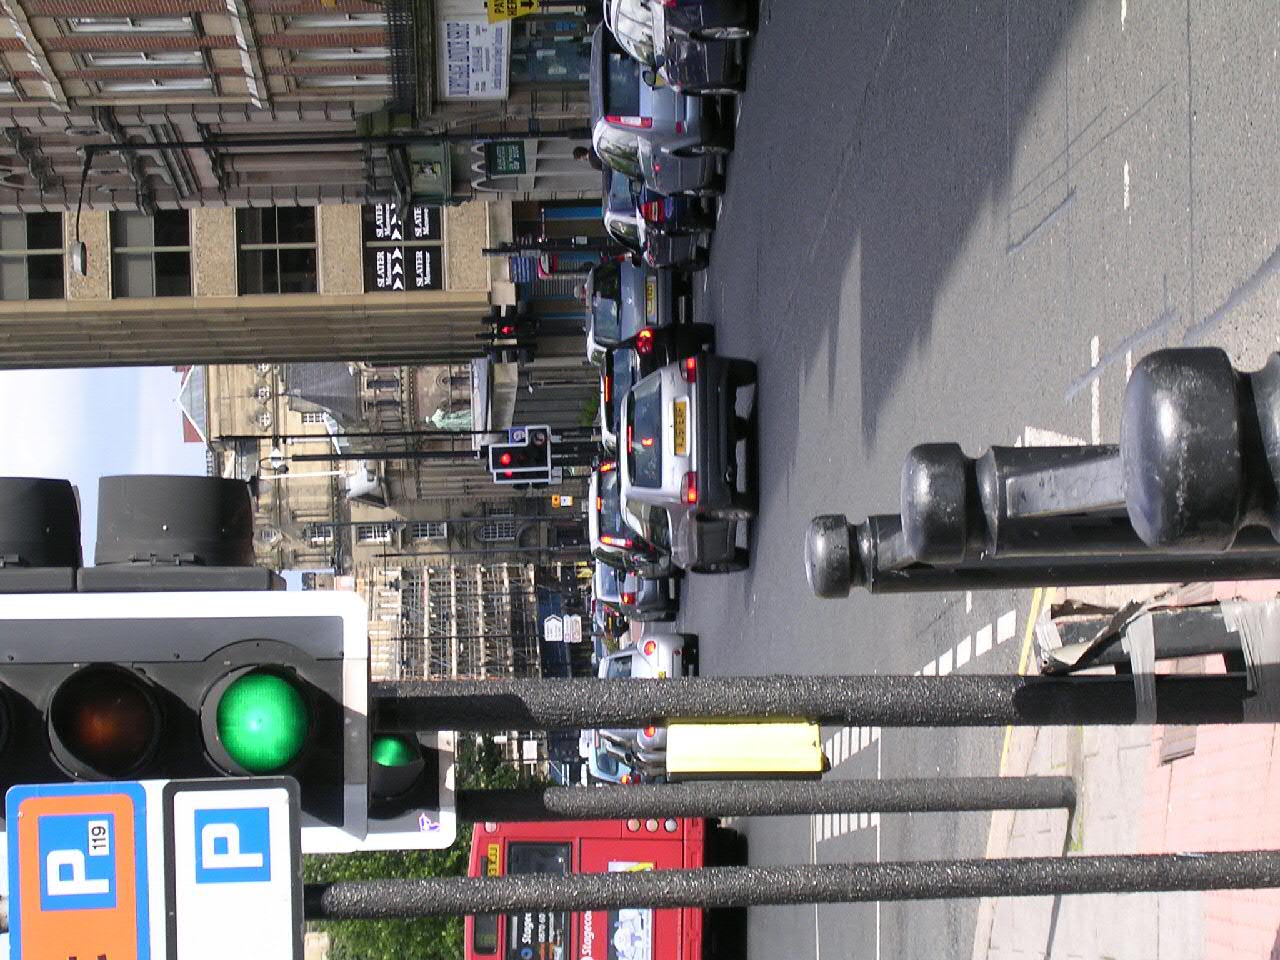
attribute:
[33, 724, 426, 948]
signs — parking